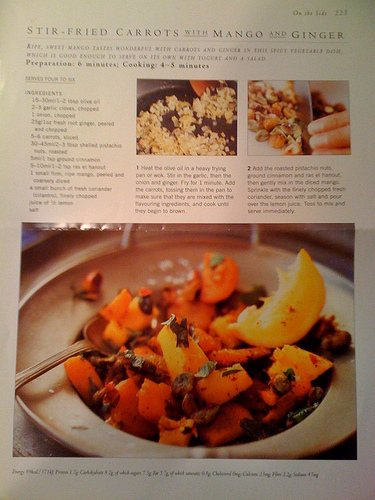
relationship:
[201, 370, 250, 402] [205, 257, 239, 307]
carrot positioned carrot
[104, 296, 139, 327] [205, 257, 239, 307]
carrot positioned carrot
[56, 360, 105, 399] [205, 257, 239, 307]
carrot positioned carrot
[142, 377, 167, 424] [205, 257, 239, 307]
carrot positioned carrot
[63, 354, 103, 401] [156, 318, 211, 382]
food placed food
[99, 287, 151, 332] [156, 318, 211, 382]
carrot placed food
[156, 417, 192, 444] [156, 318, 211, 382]
food placed food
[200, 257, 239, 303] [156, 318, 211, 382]
carrot placed food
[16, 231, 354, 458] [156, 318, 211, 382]
plate placed food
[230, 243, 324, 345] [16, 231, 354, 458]
slice on plate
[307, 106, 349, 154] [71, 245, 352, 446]
hand chopping food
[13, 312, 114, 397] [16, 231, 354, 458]
spoon on side of plate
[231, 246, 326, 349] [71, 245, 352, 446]
lemon wedge resting on food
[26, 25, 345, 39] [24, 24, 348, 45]
name of dish